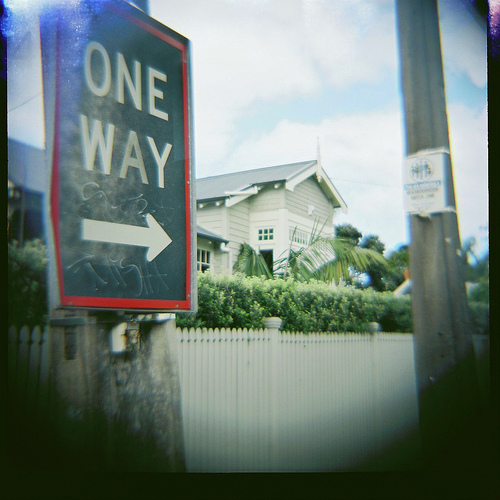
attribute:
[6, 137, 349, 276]
house — white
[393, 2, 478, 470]
pole — brown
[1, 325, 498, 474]
fence — white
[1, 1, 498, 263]
sky — blue